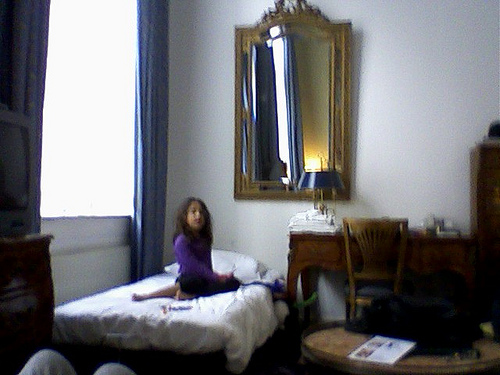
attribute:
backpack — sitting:
[355, 286, 485, 353]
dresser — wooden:
[462, 142, 497, 287]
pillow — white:
[172, 241, 256, 280]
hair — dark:
[170, 196, 213, 251]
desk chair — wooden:
[341, 217, 411, 300]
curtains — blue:
[134, 25, 184, 309]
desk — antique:
[283, 196, 498, 336]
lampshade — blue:
[289, 167, 349, 197]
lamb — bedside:
[297, 148, 344, 199]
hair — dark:
[167, 192, 219, 259]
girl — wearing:
[150, 193, 240, 295]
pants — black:
[168, 267, 245, 297]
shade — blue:
[292, 163, 343, 193]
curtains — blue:
[4, 2, 167, 284]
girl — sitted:
[124, 193, 245, 309]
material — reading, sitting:
[346, 332, 416, 368]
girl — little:
[168, 192, 242, 297]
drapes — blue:
[126, 5, 184, 283]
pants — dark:
[179, 274, 241, 297]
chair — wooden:
[341, 206, 415, 334]